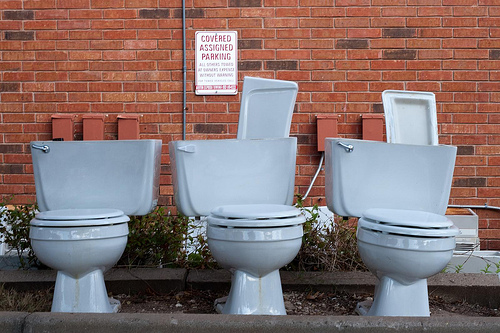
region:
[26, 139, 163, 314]
White toilet sitting outside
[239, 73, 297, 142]
White lid for toilet tank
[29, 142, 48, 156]
Chrome flush handle on toilet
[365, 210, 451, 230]
Seat cover on top of toilet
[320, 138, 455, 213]
White porcelain toilet tank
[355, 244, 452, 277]
White bowl of toilet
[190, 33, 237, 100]
White sign on brick building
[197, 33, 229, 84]
Red words on sign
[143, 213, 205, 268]
Green plants between toilets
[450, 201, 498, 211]
Metal pipe on wall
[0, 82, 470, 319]
white toilets sitting outside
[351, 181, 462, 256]
top of the toilet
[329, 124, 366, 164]
handle on the toilet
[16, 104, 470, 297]
three toilets in photo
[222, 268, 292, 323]
bottom of the photo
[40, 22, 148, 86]
red wall in the background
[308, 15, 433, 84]
dark colored bricks on wall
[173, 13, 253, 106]
sign on the building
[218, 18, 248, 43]
corner of the sign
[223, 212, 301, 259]
reflection on the toilet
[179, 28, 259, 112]
sign hanging on the building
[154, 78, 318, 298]
toilet on the ground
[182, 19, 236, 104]
the sign is white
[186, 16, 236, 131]
letters on the sign are red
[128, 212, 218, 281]
weeds next to the toilets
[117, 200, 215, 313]
the weeds are green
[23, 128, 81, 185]
the handle is silver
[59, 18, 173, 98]
building made of bricks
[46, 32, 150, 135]
the bricks are red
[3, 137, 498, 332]
Three gray toilets set side by side on a curb.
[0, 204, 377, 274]
Bushes behind the toilets.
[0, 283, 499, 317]
Dry brown leaves on the ground around the toilets.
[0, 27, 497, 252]
A brick wall behind the toilets.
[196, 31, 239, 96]
Red and white parking sign on the brick wall.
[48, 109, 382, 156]
Brown electrical boxes on the wall.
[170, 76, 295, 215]
Toilet tank lid sticking out of the tank.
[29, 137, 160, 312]
Toilet with no tank lid.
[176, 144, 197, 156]
Metal flushing handle on the front ofthe tank.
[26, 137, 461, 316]
Toilet bowls with the lids down.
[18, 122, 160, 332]
white toilet outside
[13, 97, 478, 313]
three toilets in front of a wall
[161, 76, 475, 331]
toilets in front of a wall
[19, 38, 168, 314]
toilet in front of a brick wall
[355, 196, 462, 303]
toilet with the seat down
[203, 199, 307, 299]
closed toilet cover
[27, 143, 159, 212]
toilet tank with silver handle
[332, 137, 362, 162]
silver flush handle on a toilet